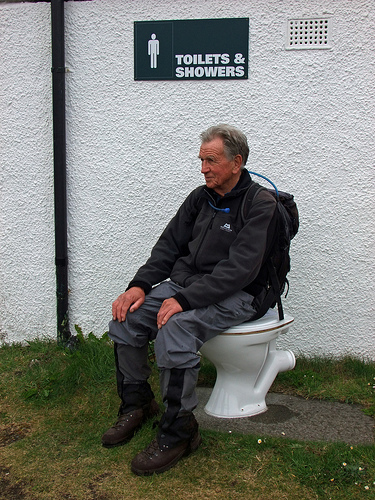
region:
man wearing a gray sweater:
[134, 157, 277, 279]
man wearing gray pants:
[102, 271, 242, 375]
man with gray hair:
[190, 126, 256, 187]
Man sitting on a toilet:
[88, 114, 308, 442]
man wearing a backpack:
[240, 171, 302, 325]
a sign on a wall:
[110, 7, 262, 101]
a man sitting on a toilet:
[155, 133, 315, 383]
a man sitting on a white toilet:
[146, 122, 285, 391]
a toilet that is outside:
[139, 166, 310, 454]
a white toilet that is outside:
[182, 302, 306, 426]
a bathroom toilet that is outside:
[207, 307, 304, 434]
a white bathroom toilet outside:
[170, 298, 314, 453]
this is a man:
[68, 115, 312, 473]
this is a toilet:
[182, 267, 310, 438]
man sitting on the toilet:
[57, 94, 328, 492]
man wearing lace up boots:
[88, 384, 201, 477]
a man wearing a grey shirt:
[97, 261, 253, 407]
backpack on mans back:
[253, 158, 314, 317]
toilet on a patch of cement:
[178, 258, 372, 460]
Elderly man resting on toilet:
[100, 121, 299, 474]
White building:
[0, 2, 373, 360]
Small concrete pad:
[188, 384, 374, 445]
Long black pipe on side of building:
[50, 0, 72, 340]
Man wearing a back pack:
[102, 122, 297, 473]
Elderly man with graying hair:
[103, 123, 295, 470]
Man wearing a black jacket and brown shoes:
[103, 124, 300, 474]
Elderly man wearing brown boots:
[105, 123, 293, 472]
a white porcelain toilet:
[197, 306, 302, 421]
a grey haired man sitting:
[83, 122, 305, 477]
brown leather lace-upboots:
[99, 395, 204, 480]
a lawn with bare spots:
[2, 337, 373, 497]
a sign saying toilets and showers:
[127, 18, 251, 84]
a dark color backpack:
[251, 172, 302, 320]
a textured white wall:
[2, 3, 374, 362]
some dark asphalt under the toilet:
[169, 382, 373, 451]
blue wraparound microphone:
[196, 168, 280, 214]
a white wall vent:
[280, 17, 332, 52]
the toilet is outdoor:
[204, 303, 305, 434]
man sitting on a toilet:
[83, 116, 307, 479]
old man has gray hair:
[122, 108, 316, 292]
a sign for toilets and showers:
[116, 9, 263, 90]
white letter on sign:
[174, 53, 183, 63]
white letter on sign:
[182, 52, 193, 64]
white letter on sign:
[190, 53, 198, 65]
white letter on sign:
[196, 53, 205, 65]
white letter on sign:
[205, 53, 213, 64]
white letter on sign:
[212, 53, 221, 64]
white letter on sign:
[219, 52, 230, 67]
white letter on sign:
[174, 64, 184, 79]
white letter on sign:
[185, 65, 196, 78]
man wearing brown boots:
[92, 390, 205, 471]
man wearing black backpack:
[247, 170, 298, 315]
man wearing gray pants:
[104, 253, 244, 409]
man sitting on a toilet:
[52, 116, 312, 442]